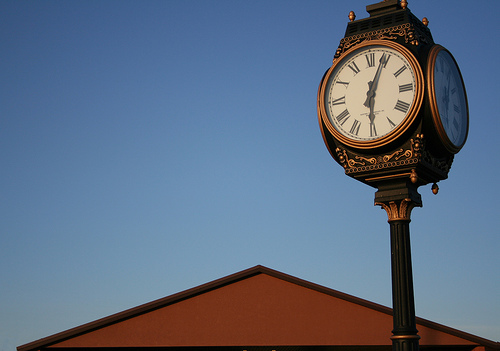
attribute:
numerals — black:
[380, 61, 415, 113]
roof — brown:
[19, 263, 389, 346]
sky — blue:
[81, 7, 279, 76]